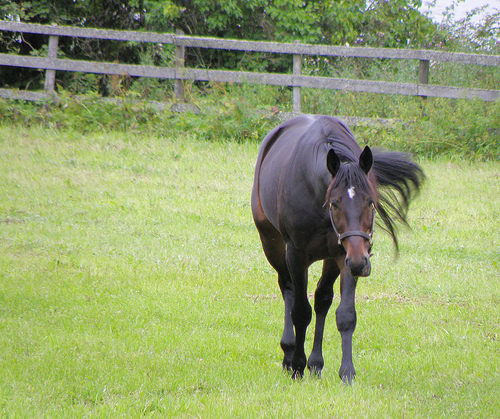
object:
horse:
[248, 115, 430, 390]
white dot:
[347, 182, 357, 199]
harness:
[328, 207, 381, 244]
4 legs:
[253, 227, 386, 378]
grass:
[0, 110, 500, 386]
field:
[0, 112, 500, 387]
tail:
[362, 137, 424, 256]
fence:
[278, 39, 436, 114]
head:
[324, 143, 378, 277]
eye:
[365, 195, 377, 211]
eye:
[328, 196, 342, 213]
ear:
[326, 144, 347, 177]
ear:
[357, 145, 374, 176]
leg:
[284, 245, 319, 375]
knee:
[290, 288, 322, 330]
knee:
[276, 279, 289, 292]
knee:
[335, 301, 363, 332]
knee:
[315, 275, 333, 315]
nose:
[341, 245, 368, 275]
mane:
[329, 142, 373, 201]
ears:
[322, 145, 373, 178]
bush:
[6, 66, 495, 165]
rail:
[4, 29, 499, 118]